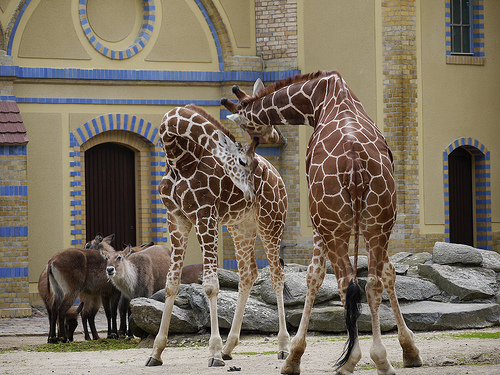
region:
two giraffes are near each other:
[127, 90, 404, 292]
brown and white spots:
[285, 87, 424, 292]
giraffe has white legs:
[147, 231, 294, 350]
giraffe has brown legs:
[294, 220, 433, 350]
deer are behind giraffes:
[42, 228, 204, 350]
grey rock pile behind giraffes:
[157, 230, 494, 331]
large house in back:
[11, 3, 264, 261]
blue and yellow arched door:
[60, 100, 163, 227]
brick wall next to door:
[0, 142, 30, 312]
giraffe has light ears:
[223, 95, 253, 135]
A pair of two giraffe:
[143, 66, 427, 373]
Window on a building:
[440, 0, 489, 67]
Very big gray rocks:
[124, 238, 498, 336]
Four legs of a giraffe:
[143, 221, 293, 368]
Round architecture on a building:
[72, 0, 157, 63]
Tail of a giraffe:
[330, 185, 369, 371]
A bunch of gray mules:
[37, 232, 204, 346]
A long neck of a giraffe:
[157, 102, 237, 164]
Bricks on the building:
[252, 2, 300, 61]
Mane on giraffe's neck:
[240, 68, 324, 109]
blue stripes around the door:
[77, 115, 154, 132]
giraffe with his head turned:
[143, 100, 295, 373]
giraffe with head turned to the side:
[229, 72, 424, 374]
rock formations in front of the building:
[406, 240, 498, 330]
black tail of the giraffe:
[340, 274, 364, 371]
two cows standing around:
[38, 235, 137, 345]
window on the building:
[450, 3, 471, 58]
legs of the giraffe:
[141, 278, 293, 373]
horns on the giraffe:
[215, 83, 244, 112]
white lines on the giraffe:
[320, 108, 367, 141]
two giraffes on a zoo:
[145, 66, 419, 371]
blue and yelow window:
[442, 6, 486, 66]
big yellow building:
[4, 0, 498, 308]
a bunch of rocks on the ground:
[126, 237, 496, 330]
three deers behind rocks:
[33, 230, 196, 341]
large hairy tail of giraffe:
[332, 187, 365, 371]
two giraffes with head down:
[140, 69, 420, 373]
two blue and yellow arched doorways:
[67, 115, 494, 270]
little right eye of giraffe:
[235, 157, 250, 169]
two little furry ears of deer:
[95, 244, 134, 259]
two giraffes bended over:
[109, 81, 409, 264]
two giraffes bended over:
[142, 67, 343, 199]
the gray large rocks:
[424, 207, 478, 331]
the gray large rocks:
[250, 206, 493, 358]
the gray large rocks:
[129, 209, 304, 359]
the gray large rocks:
[282, 198, 424, 332]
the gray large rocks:
[377, 203, 472, 367]